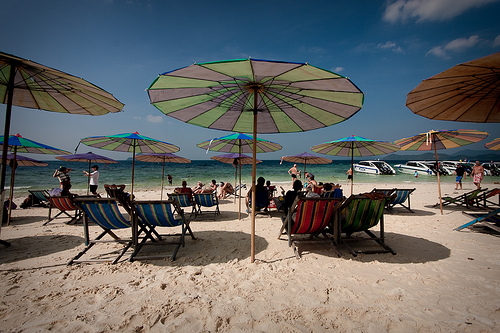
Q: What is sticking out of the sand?
A: An umbrella.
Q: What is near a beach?
A: A body of water.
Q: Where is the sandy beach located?
A: Under a blue sky.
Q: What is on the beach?
A: A lawn chair.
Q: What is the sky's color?
A: Dark blue.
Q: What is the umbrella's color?
A: Red and yellow.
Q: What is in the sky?
A: Clouds.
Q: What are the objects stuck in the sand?
A: Big umbrellas.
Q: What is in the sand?
A: Big umbrellas.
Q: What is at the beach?
A: Several umbrellas.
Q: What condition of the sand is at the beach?
A: Soft.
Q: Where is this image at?
A: Beach.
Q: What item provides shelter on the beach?
A: A umbrella.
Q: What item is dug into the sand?
A: A umbrella.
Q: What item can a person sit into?
A: A chair.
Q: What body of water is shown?
A: The ocean.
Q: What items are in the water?
A: A boat.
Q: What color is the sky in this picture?
A: Blue.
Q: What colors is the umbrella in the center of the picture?
A: Green and Purple.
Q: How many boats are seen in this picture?
A: Four.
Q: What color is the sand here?
A: Tan.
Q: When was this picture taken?
A: Daytime.